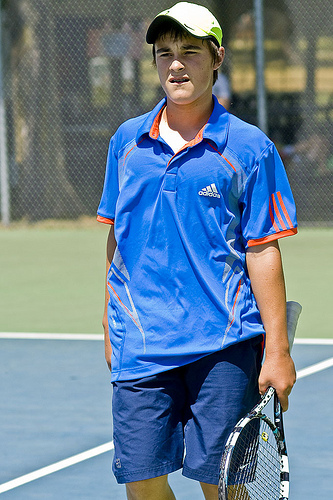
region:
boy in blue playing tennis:
[84, 36, 332, 422]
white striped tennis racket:
[209, 377, 316, 496]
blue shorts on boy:
[116, 358, 305, 486]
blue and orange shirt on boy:
[84, 166, 264, 363]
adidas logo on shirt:
[197, 177, 239, 216]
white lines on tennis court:
[20, 443, 72, 495]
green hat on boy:
[142, 9, 210, 46]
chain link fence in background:
[37, 83, 327, 271]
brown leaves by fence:
[34, 202, 114, 237]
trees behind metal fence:
[272, 18, 331, 135]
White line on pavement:
[3, 464, 57, 499]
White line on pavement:
[58, 439, 127, 476]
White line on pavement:
[293, 361, 332, 404]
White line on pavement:
[1, 315, 89, 357]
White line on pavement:
[301, 330, 329, 358]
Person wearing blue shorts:
[83, 350, 258, 498]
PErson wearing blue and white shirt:
[92, 87, 272, 394]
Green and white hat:
[110, 7, 234, 64]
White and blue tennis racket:
[210, 389, 305, 497]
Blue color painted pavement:
[15, 369, 52, 429]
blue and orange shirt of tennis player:
[89, 106, 304, 358]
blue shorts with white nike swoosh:
[104, 343, 262, 486]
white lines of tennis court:
[2, 327, 326, 499]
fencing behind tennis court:
[2, 3, 323, 229]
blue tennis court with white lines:
[0, 331, 332, 499]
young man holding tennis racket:
[92, 3, 289, 497]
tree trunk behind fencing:
[10, 2, 82, 218]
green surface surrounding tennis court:
[5, 231, 331, 328]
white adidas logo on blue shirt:
[193, 176, 220, 202]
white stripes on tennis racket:
[215, 410, 295, 499]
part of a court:
[303, 424, 307, 430]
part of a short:
[205, 399, 213, 419]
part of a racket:
[244, 467, 249, 480]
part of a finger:
[267, 366, 269, 368]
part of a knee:
[141, 476, 145, 482]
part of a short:
[145, 461, 148, 466]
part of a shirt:
[144, 351, 149, 359]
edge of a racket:
[236, 443, 246, 455]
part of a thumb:
[267, 375, 273, 381]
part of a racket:
[259, 390, 288, 442]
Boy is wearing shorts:
[107, 330, 263, 484]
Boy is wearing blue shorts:
[109, 329, 260, 485]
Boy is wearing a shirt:
[95, 91, 302, 382]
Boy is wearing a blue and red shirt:
[96, 94, 301, 382]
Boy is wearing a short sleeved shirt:
[93, 96, 282, 383]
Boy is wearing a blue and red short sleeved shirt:
[94, 94, 296, 384]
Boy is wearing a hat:
[141, 0, 226, 50]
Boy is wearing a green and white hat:
[142, 0, 224, 52]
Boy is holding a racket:
[215, 296, 306, 498]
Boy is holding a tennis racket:
[215, 299, 303, 498]